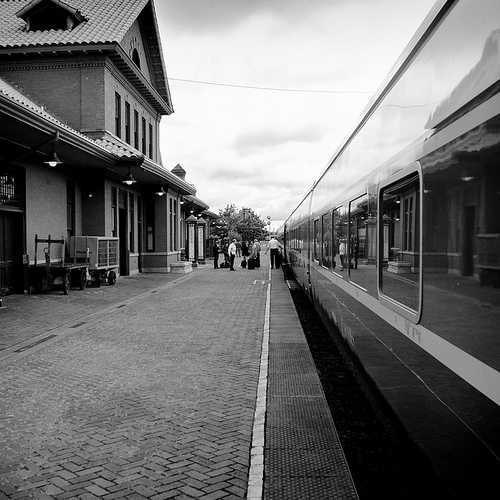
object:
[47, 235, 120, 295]
cart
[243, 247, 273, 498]
line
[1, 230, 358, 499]
road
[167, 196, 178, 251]
window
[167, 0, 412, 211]
clouds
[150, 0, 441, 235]
sky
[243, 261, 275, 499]
white line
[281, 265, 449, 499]
gap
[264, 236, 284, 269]
man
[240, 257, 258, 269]
luggage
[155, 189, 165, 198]
light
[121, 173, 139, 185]
light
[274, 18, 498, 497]
train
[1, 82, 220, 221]
awning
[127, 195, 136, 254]
window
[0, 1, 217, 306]
building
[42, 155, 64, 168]
light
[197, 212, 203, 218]
light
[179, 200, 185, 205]
light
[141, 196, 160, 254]
window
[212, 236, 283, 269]
people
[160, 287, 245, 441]
plane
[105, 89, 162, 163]
windows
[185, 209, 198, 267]
pole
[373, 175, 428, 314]
window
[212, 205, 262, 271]
trees/people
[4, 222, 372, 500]
platform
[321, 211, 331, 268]
window